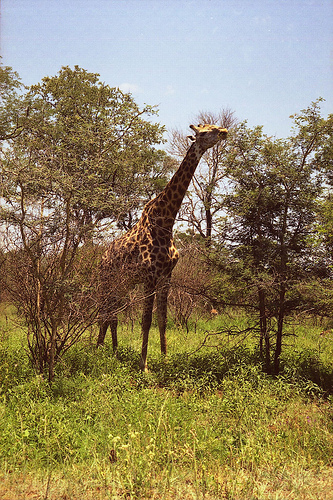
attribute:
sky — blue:
[0, 0, 331, 273]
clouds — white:
[95, 77, 147, 101]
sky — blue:
[130, 10, 302, 98]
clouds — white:
[101, 62, 273, 143]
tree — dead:
[0, 62, 172, 391]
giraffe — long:
[51, 68, 268, 426]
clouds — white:
[203, 5, 297, 46]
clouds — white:
[113, 73, 230, 106]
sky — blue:
[30, 23, 314, 116]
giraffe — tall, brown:
[97, 120, 230, 372]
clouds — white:
[157, 60, 187, 101]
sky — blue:
[63, 9, 312, 73]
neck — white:
[154, 140, 203, 222]